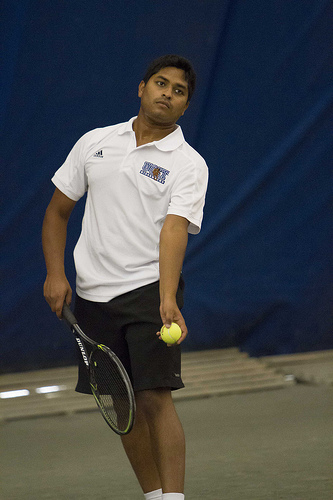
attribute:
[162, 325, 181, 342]
ball — yellow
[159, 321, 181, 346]
tennis ball — bright, green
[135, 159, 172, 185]
logo — black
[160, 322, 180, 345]
ball — yellow 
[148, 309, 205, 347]
ball — yellow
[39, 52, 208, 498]
man — dark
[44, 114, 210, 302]
shirt — white, polo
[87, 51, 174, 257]
man — young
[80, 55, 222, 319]
tennis player — male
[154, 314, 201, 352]
ball — green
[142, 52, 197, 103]
hair — short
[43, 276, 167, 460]
racquet — green , black 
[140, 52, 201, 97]
hair — brown 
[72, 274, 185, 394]
shorts — black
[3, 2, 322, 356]
backdrop — blue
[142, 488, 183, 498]
socks — white